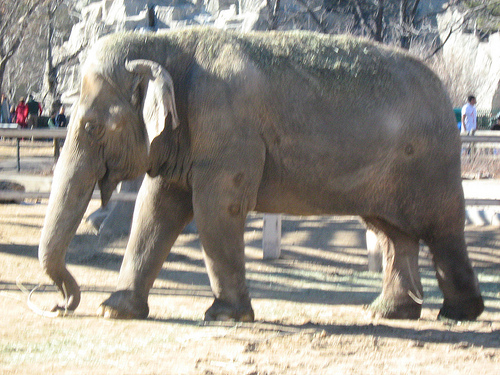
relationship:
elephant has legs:
[46, 17, 476, 315] [437, 239, 481, 320]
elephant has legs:
[46, 17, 476, 315] [374, 244, 416, 316]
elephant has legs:
[46, 17, 476, 315] [191, 172, 255, 320]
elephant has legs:
[46, 17, 476, 315] [108, 180, 188, 317]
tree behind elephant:
[297, 4, 459, 87] [46, 17, 476, 315]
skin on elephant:
[105, 128, 192, 180] [31, 20, 491, 329]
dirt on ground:
[251, 331, 321, 364] [6, 310, 496, 372]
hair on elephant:
[255, 24, 390, 84] [31, 20, 491, 329]